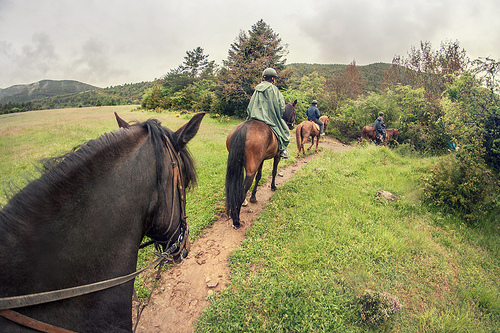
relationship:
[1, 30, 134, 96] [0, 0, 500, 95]
cloud in sky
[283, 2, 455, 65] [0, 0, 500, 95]
cloud in sky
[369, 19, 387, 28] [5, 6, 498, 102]
clouds in sky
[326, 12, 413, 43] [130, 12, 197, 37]
clouds in sky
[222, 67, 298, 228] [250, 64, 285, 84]
people wearing helmets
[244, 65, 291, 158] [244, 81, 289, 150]
person in jacket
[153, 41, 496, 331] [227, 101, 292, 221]
people riding horses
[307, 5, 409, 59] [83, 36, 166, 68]
clouds in sky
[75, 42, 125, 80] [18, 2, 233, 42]
clouds in sky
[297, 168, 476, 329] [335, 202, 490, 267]
ground has grass